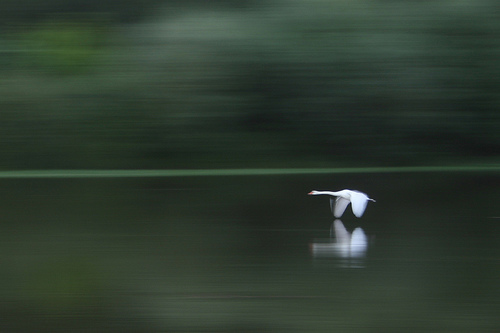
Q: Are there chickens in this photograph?
A: No, there are no chickens.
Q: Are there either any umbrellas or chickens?
A: No, there are no chickens or umbrellas.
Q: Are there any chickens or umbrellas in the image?
A: No, there are no chickens or umbrellas.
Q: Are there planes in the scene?
A: No, there are no planes.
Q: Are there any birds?
A: Yes, there is a bird.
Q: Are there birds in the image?
A: Yes, there is a bird.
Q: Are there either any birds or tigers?
A: Yes, there is a bird.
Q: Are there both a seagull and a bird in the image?
A: No, there is a bird but no seagulls.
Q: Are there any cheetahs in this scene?
A: No, there are no cheetahs.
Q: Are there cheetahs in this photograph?
A: No, there are no cheetahs.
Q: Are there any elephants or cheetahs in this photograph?
A: No, there are no cheetahs or elephants.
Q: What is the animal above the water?
A: The animal is a bird.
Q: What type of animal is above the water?
A: The animal is a bird.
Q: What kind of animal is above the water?
A: The animal is a bird.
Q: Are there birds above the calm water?
A: Yes, there is a bird above the water.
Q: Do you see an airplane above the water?
A: No, there is a bird above the water.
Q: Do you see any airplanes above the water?
A: No, there is a bird above the water.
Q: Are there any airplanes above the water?
A: No, there is a bird above the water.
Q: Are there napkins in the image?
A: No, there are no napkins.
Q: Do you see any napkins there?
A: No, there are no napkins.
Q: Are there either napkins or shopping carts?
A: No, there are no napkins or shopping carts.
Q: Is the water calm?
A: Yes, the water is calm.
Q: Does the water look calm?
A: Yes, the water is calm.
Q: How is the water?
A: The water is calm.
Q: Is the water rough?
A: No, the water is calm.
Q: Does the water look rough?
A: No, the water is calm.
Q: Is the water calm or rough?
A: The water is calm.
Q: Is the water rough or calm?
A: The water is calm.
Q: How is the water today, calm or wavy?
A: The water is calm.